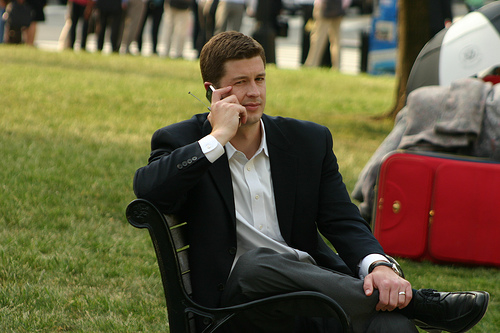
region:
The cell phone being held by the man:
[185, 84, 245, 127]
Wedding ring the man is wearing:
[396, 290, 406, 297]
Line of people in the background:
[1, 0, 391, 65]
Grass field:
[1, 43, 498, 331]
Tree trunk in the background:
[388, 0, 445, 120]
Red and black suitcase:
[369, 147, 499, 272]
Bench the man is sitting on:
[104, 195, 359, 332]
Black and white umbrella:
[400, 0, 498, 92]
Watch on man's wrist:
[368, 258, 404, 278]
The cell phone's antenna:
[184, 89, 209, 111]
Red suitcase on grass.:
[367, 137, 499, 276]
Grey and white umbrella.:
[401, 3, 498, 89]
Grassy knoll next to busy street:
[4, 0, 180, 331]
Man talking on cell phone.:
[116, 23, 315, 230]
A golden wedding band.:
[353, 257, 428, 319]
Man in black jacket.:
[132, 25, 400, 330]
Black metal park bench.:
[70, 200, 352, 330]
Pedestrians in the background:
[2, 0, 410, 72]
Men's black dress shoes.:
[410, 281, 492, 331]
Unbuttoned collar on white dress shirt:
[192, 118, 310, 277]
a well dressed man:
[126, 32, 494, 332]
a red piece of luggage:
[369, 148, 499, 273]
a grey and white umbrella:
[393, 1, 498, 98]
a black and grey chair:
[120, 192, 351, 331]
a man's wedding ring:
[397, 288, 406, 295]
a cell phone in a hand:
[202, 82, 242, 128]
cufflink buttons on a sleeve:
[176, 155, 201, 170]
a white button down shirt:
[195, 110, 322, 282]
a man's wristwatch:
[368, 257, 404, 277]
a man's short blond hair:
[198, 30, 268, 91]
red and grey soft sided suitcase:
[368, 142, 498, 267]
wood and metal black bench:
[125, 183, 391, 328]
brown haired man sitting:
[139, 24, 488, 327]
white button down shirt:
[198, 114, 320, 260]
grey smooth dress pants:
[232, 244, 417, 329]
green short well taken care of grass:
[0, 40, 498, 327]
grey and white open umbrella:
[397, 32, 495, 92]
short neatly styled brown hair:
[201, 29, 263, 89]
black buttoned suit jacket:
[127, 112, 386, 272]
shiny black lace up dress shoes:
[412, 284, 485, 329]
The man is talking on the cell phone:
[185, 40, 307, 140]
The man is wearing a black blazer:
[136, 123, 401, 280]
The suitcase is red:
[376, 156, 498, 284]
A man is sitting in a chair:
[118, 31, 456, 330]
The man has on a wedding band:
[352, 259, 466, 314]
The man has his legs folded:
[224, 218, 484, 327]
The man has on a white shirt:
[170, 86, 359, 277]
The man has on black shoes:
[369, 247, 494, 319]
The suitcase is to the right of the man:
[356, 93, 498, 288]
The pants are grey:
[223, 244, 447, 330]